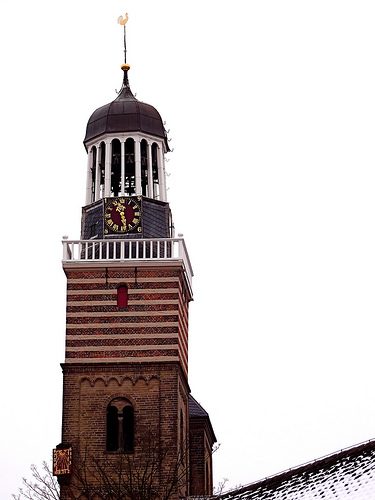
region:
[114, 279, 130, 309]
small red arched window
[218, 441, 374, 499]
sloping section of roof with snow on it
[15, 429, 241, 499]
top of a brown bare tree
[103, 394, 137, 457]
double window with an arch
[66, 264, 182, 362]
white and red brick section of tower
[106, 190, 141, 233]
red black and gold clock face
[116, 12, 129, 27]
small gold rooster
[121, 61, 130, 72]
small round gold ball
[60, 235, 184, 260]
bright white railing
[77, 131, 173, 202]
white spires holding tower bell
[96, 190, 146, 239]
clock on building tower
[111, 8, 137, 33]
chicken on top of building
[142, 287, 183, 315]
several bricks in design on side of building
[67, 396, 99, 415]
bricks on side of building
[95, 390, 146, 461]
window on side of brick building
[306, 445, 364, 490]
roof shingles on building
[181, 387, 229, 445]
roof of brick building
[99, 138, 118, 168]
white posts on roof of building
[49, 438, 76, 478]
design on side of building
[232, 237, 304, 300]
clear sky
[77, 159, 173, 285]
a clock on a building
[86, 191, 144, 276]
a large clock on a building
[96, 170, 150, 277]
an outside clock on a building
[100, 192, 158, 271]
a large outside clock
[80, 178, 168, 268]
a building with a large clock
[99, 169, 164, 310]
a building with a clock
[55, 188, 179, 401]
a tall building with clock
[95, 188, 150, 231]
a clock on a building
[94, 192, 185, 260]
a large clock on building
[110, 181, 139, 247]
a large outside clock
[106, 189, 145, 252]
a building with large clock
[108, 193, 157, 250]
a building with outside clock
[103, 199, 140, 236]
clock on the tower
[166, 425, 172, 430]
brick on the tower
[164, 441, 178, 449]
brick on the tower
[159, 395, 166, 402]
brick on the tower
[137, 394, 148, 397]
brick on the tower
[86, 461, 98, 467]
brick on the tower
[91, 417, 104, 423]
brick on the tower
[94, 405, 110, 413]
brick on the tower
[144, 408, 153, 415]
brick on the tower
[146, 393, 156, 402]
brick on the tower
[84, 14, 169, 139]
weather vane on dome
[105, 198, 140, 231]
gold numbers on clock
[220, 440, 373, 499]
snow on slanted roof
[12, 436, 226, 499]
branches with no leaves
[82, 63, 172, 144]
gold ball on dome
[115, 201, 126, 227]
gold hands of clock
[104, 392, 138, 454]
arched shaped tower window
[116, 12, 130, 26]
brass colored bird figurine